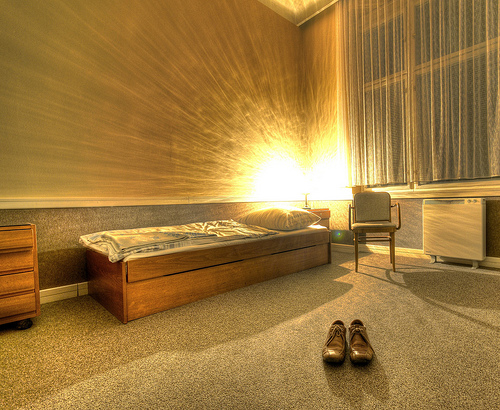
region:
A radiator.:
[415, 191, 492, 273]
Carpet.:
[72, 325, 262, 397]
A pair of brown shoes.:
[295, 290, 400, 391]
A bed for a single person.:
[70, 190, 335, 330]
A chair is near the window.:
[345, 32, 460, 277]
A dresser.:
[0, 215, 42, 325]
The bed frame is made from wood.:
[77, 186, 332, 321]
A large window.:
[325, 5, 495, 190]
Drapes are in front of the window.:
[330, 0, 490, 185]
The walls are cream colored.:
[42, 26, 178, 148]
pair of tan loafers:
[310, 314, 392, 371]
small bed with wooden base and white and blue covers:
[71, 207, 338, 324]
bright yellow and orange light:
[225, 120, 355, 210]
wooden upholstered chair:
[344, 184, 409, 277]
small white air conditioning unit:
[410, 190, 492, 279]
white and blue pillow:
[233, 202, 328, 238]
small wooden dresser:
[0, 217, 55, 331]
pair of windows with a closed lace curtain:
[325, 2, 497, 185]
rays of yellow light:
[10, 0, 238, 199]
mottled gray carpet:
[137, 327, 293, 402]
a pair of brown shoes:
[320, 321, 380, 366]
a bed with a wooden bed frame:
[84, 193, 338, 313]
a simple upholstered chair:
[349, 188, 409, 269]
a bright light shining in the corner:
[255, 121, 342, 216]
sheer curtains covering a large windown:
[340, 22, 483, 193]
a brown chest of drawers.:
[2, 215, 49, 347]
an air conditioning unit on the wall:
[417, 188, 497, 284]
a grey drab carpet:
[129, 323, 293, 405]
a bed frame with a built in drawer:
[123, 224, 343, 288]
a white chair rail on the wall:
[25, 193, 243, 215]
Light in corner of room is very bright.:
[231, 126, 351, 206]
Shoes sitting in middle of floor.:
[316, 314, 383, 366]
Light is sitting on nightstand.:
[296, 205, 339, 262]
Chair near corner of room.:
[348, 184, 408, 278]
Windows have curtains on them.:
[342, 31, 499, 183]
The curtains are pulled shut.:
[336, 28, 498, 192]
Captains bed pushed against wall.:
[60, 200, 342, 327]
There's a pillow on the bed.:
[233, 202, 320, 238]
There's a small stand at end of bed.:
[1, 220, 51, 333]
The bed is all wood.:
[70, 223, 345, 328]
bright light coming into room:
[217, 108, 381, 206]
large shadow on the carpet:
[55, 327, 227, 374]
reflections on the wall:
[165, 51, 232, 111]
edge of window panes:
[343, 36, 498, 106]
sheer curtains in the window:
[328, 1, 499, 198]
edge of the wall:
[13, 178, 120, 222]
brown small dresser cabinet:
[4, 213, 71, 328]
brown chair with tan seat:
[338, 186, 430, 280]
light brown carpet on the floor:
[60, 338, 254, 400]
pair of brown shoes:
[315, 302, 380, 377]